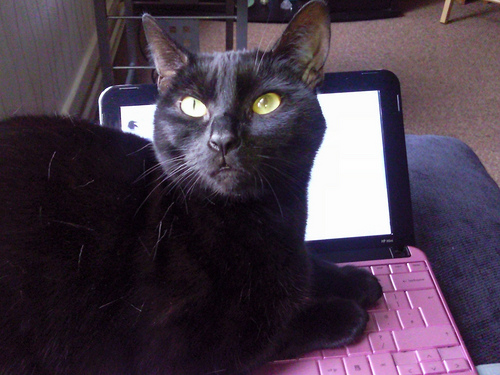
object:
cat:
[0, 0, 384, 375]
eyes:
[176, 94, 206, 118]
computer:
[93, 70, 473, 375]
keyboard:
[215, 260, 472, 375]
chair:
[197, 135, 500, 375]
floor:
[116, 0, 500, 186]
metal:
[90, 1, 251, 93]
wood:
[442, 0, 499, 25]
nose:
[207, 131, 244, 153]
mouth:
[207, 158, 245, 180]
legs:
[264, 298, 323, 363]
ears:
[136, 13, 195, 87]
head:
[134, 0, 328, 196]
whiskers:
[134, 152, 204, 216]